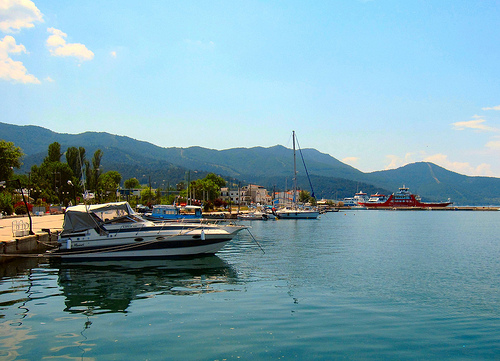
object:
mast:
[289, 129, 298, 210]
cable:
[239, 224, 267, 254]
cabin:
[147, 202, 202, 222]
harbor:
[0, 203, 499, 258]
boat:
[36, 200, 251, 263]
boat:
[140, 199, 204, 226]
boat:
[273, 130, 321, 219]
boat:
[355, 183, 455, 211]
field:
[0, 185, 225, 218]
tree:
[24, 157, 76, 207]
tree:
[43, 141, 62, 164]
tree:
[0, 138, 27, 189]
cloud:
[40, 27, 94, 63]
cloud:
[0, 0, 46, 33]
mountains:
[0, 121, 499, 206]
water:
[0, 208, 499, 360]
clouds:
[0, 33, 40, 87]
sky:
[0, 0, 498, 180]